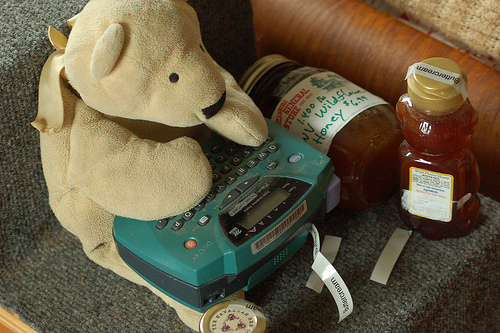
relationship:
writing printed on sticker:
[329, 274, 349, 314] [302, 220, 354, 323]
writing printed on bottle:
[269, 84, 369, 148] [236, 50, 405, 211]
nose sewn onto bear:
[199, 90, 227, 120] [28, 0, 269, 332]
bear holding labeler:
[28, 0, 269, 332] [112, 116, 344, 315]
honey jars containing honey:
[239, 50, 402, 210] [249, 61, 404, 213]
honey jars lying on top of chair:
[239, 50, 402, 210] [1, 1, 483, 329]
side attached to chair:
[252, 1, 483, 200] [1, 1, 483, 329]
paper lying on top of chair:
[302, 233, 340, 293] [1, 1, 483, 329]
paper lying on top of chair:
[367, 225, 413, 284] [1, 1, 483, 329]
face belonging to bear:
[118, 6, 227, 128] [28, 1, 270, 331]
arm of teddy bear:
[64, 125, 209, 221] [40, 0, 314, 330]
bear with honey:
[28, 0, 323, 329] [243, 35, 483, 238]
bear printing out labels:
[28, 0, 323, 329] [273, 203, 368, 325]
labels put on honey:
[273, 203, 368, 325] [243, 35, 483, 238]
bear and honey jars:
[28, 0, 269, 332] [223, 32, 474, 234]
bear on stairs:
[28, 0, 269, 332] [2, 6, 496, 331]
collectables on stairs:
[35, 8, 482, 329] [2, 6, 496, 331]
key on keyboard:
[261, 135, 284, 156] [101, 110, 357, 315]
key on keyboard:
[232, 163, 250, 177] [101, 110, 357, 315]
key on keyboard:
[221, 166, 242, 182] [101, 110, 357, 315]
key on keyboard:
[221, 186, 235, 200] [101, 110, 357, 315]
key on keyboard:
[172, 215, 184, 229] [106, 114, 342, 317]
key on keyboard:
[206, 192, 220, 202] [101, 110, 357, 315]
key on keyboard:
[222, 150, 234, 157] [101, 110, 357, 315]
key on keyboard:
[252, 143, 272, 163] [101, 110, 357, 315]